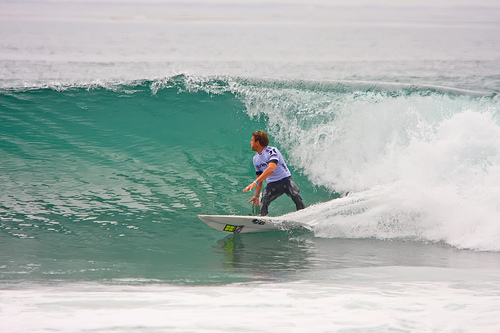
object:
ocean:
[0, 1, 500, 333]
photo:
[0, 2, 500, 333]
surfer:
[241, 130, 307, 217]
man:
[242, 130, 307, 218]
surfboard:
[197, 213, 314, 234]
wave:
[214, 73, 499, 254]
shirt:
[251, 145, 292, 185]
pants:
[258, 175, 306, 217]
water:
[3, 0, 500, 331]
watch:
[253, 180, 259, 186]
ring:
[246, 186, 249, 189]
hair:
[251, 130, 270, 148]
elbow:
[267, 166, 275, 173]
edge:
[0, 74, 500, 100]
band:
[253, 194, 260, 197]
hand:
[242, 183, 256, 193]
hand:
[248, 195, 261, 208]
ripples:
[176, 147, 237, 214]